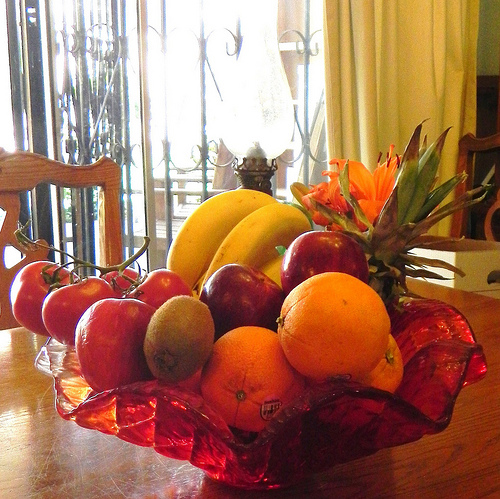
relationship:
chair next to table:
[0, 142, 128, 332] [3, 269, 498, 496]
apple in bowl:
[199, 257, 282, 327] [32, 293, 487, 490]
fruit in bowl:
[171, 185, 283, 275] [32, 293, 487, 490]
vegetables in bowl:
[6, 258, 172, 325] [32, 293, 487, 490]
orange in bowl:
[267, 270, 398, 413] [59, 385, 466, 482]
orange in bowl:
[211, 332, 292, 422] [59, 385, 466, 482]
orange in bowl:
[367, 331, 410, 396] [59, 385, 466, 482]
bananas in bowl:
[164, 187, 311, 297] [15, 285, 472, 496]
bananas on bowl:
[164, 187, 311, 297] [32, 293, 487, 490]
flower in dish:
[329, 151, 398, 199] [21, 291, 492, 485]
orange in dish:
[267, 270, 398, 413] [21, 291, 492, 485]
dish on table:
[21, 291, 492, 485] [75, 106, 499, 468]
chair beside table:
[0, 142, 128, 332] [3, 269, 498, 496]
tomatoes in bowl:
[10, 258, 85, 333] [32, 293, 487, 490]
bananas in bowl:
[164, 187, 311, 297] [32, 293, 487, 490]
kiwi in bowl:
[140, 292, 213, 382] [30, 365, 489, 480]